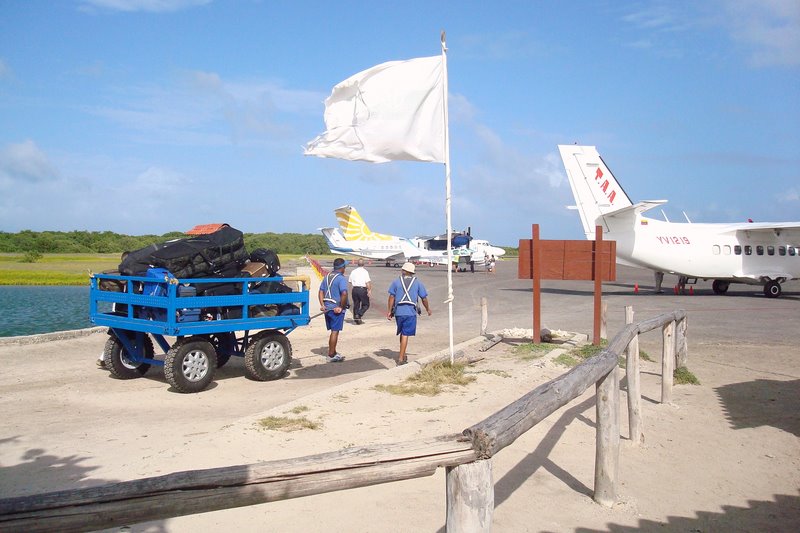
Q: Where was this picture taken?
A: At an airport.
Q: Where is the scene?
A: At an airport.